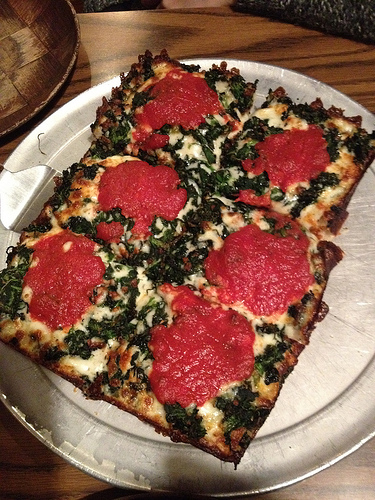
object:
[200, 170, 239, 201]
basil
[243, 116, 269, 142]
basil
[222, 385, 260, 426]
basil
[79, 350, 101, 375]
cheese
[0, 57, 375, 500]
plate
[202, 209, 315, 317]
sauce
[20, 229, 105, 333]
sauce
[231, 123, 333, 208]
sauce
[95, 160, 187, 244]
sauce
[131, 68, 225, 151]
sauce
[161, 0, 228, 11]
hand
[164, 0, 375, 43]
person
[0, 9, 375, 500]
table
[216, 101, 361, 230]
yellow ladder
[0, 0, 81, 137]
bowl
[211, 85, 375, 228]
slice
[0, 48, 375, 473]
pizza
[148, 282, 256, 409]
red sauce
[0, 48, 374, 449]
spinach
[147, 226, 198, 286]
basil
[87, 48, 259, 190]
slice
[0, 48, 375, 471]
flat bread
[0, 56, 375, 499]
baking pan